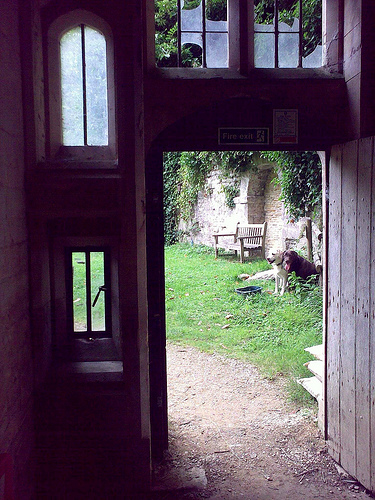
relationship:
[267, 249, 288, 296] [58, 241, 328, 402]
canine outside grass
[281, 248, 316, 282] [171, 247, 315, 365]
canine outside space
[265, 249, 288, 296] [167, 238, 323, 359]
canine outside space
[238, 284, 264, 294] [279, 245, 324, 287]
container in front of canine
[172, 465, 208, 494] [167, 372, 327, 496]
rocks on ground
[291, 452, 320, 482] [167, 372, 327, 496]
sticks on ground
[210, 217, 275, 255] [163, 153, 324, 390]
bench in outdoors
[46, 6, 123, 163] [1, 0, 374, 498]
arched window in building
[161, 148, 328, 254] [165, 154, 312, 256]
plant growing along wall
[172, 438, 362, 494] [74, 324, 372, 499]
rocks on path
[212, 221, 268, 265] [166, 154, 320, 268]
bench along wall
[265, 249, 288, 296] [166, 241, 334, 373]
canine sitting in grass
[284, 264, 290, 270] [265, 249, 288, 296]
tongue sticking out of canine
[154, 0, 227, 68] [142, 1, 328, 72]
glass in window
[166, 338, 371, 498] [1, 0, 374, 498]
dirt inside building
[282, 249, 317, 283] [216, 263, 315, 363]
canine in grass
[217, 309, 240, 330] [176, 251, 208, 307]
leaves on grass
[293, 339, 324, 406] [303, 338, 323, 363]
stack of bag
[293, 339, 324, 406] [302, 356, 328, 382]
stack of bag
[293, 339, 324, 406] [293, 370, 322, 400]
stack of bag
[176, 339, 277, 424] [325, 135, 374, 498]
dirt path from door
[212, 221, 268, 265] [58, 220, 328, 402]
bench on grass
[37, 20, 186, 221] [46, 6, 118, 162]
sunlight through arched window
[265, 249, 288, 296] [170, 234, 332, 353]
canine yard yard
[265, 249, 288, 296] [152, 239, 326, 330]
canine in yard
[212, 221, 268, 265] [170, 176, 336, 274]
bench against wall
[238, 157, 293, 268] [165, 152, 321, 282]
arc in wall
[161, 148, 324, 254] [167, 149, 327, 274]
plant on wall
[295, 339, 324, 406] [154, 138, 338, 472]
stack outside door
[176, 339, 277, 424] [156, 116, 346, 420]
dirt path through door